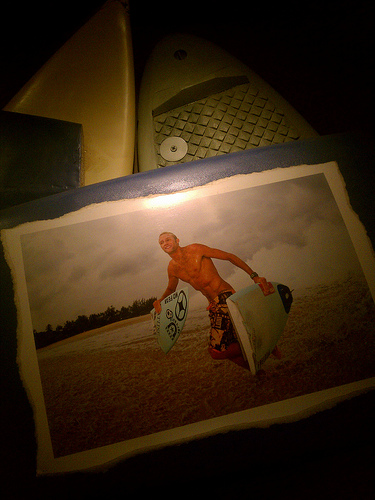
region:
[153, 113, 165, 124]
Small green diamond on board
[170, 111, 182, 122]
Small green diamond on board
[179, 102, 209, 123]
Small green diamond on board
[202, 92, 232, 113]
Small green diamond on board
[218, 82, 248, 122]
Small green diamond on board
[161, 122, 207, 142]
Small green diamond on board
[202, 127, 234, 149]
Small green diamond on board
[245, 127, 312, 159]
Small green diamond on board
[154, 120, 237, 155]
Small green diamond on board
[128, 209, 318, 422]
Man holding a broken surfboard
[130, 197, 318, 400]
A picture of a man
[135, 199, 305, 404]
a picture of a man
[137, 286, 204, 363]
a piece of surf board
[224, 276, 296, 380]
a piece of surf board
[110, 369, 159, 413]
brown sand on the ground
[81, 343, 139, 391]
brown sand on the ground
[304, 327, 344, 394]
brown sand on the ground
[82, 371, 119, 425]
brown sand on the ground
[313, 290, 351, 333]
brown sand on the ground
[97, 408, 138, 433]
brown sand on the ground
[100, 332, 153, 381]
brown sand on the ground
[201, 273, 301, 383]
a half of a surf board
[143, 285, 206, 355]
a half of a surf board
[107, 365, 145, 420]
sand in the picture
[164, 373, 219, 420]
sand in the picture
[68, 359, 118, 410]
sand in the picture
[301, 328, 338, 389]
sand in the picture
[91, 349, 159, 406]
sand in the picture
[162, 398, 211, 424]
sand in the picture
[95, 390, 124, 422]
sand in the picture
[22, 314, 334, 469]
photo of guy with surfboard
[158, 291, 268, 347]
surfboard is in 2 pieces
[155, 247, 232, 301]
man is wearing no shirt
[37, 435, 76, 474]
photo is framed in white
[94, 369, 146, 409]
sand on beach is tan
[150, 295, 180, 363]
half of surfboard with designs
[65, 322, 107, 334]
groove of green trees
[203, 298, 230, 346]
man in patterned trunks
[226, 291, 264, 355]
white interior of surfboard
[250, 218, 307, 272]
sky is gray and cloudy